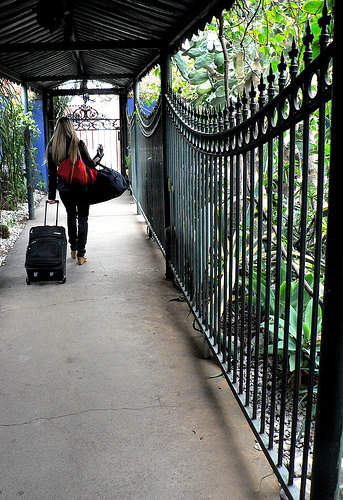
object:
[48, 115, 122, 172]
gate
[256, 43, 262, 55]
leaves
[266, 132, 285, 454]
poles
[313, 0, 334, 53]
decorative tops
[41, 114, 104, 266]
woman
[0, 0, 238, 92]
roof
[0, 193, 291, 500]
cement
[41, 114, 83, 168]
long hair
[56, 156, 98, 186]
bag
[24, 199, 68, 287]
luggage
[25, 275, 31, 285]
wheels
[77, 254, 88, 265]
shoes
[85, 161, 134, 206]
bag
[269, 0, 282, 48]
tree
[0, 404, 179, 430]
crack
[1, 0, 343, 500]
gated area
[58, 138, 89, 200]
back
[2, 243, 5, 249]
stones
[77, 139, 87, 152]
woman's shoulder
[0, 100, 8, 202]
plants